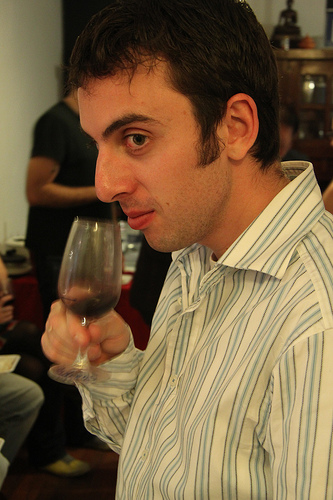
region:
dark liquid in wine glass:
[77, 292, 128, 319]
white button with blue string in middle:
[166, 371, 198, 404]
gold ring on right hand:
[37, 319, 78, 349]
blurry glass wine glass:
[50, 222, 137, 376]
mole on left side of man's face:
[159, 194, 191, 214]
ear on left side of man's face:
[223, 97, 270, 183]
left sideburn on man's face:
[188, 106, 228, 189]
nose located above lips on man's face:
[93, 150, 138, 208]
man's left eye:
[109, 122, 176, 175]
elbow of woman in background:
[25, 166, 73, 223]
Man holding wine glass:
[49, 161, 154, 385]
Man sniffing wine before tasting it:
[63, 184, 152, 257]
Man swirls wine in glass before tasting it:
[62, 276, 131, 324]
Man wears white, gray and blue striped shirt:
[223, 214, 309, 421]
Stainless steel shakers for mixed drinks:
[290, 48, 323, 109]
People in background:
[0, 249, 32, 423]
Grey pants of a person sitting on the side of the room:
[2, 361, 42, 475]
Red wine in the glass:
[55, 276, 119, 318]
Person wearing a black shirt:
[21, 92, 92, 180]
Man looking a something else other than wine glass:
[118, 122, 164, 159]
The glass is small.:
[57, 206, 130, 324]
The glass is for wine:
[53, 201, 139, 355]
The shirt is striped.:
[157, 246, 327, 499]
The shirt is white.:
[150, 322, 318, 466]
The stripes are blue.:
[137, 283, 311, 474]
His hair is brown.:
[76, 14, 267, 227]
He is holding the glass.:
[33, 288, 163, 403]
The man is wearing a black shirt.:
[17, 112, 115, 263]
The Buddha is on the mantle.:
[272, 2, 309, 60]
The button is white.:
[163, 369, 195, 397]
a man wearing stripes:
[230, 359, 285, 488]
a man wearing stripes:
[183, 419, 221, 486]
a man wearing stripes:
[200, 406, 228, 476]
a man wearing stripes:
[169, 391, 220, 492]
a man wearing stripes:
[196, 403, 210, 433]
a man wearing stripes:
[211, 469, 221, 495]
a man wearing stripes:
[180, 374, 209, 443]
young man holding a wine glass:
[41, 7, 332, 496]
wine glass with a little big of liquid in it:
[35, 208, 134, 406]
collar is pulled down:
[214, 220, 298, 297]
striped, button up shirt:
[37, 158, 329, 498]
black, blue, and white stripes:
[215, 405, 244, 499]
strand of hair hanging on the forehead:
[125, 70, 135, 98]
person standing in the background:
[8, 41, 141, 350]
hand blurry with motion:
[29, 294, 127, 386]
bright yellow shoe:
[51, 451, 94, 481]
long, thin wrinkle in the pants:
[4, 387, 35, 399]